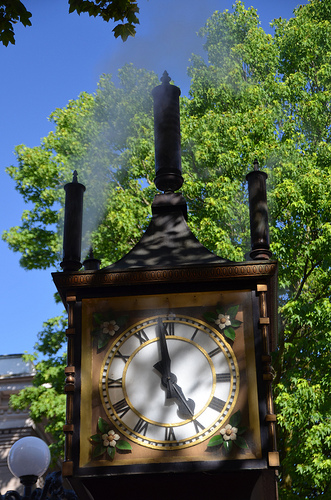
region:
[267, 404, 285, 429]
edge of a clock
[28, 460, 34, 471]
part of a bulb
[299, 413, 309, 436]
part of a tree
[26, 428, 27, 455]
edge of a light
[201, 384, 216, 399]
part of a clock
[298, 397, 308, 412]
part of a branch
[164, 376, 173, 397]
part of a watch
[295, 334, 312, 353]
part of a branch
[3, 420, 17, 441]
part of a clock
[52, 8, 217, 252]
steam in the air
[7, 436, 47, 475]
a white glass bulb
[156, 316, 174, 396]
long hand on a clock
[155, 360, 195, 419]
short hand on a clock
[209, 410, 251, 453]
green and white decorative flower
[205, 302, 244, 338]
green and white decorative flower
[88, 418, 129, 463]
green and white decorative flower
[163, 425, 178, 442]
roman numeral for 6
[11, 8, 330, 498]
a large green tree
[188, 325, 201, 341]
roman numeral for one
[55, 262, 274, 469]
Large clock on a pole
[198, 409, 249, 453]
Decorative flower on a clock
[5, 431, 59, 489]
Top of a lamp pole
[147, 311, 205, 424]
Hands on a large clock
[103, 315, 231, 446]
Roman numbers on a clock face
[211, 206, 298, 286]
Leaves of a tree in teh background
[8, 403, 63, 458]
Brick building in background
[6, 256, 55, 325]
Blue sky above a building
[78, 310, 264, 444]
Face of a clock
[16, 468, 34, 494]
Pole supporting a light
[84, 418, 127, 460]
Flower decoration in the corner of a clock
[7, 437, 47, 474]
Globe shaped light on the top of a post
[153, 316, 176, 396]
The minute hand on a clock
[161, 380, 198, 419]
The hour hand on a clock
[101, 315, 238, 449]
Black and white clock face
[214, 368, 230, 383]
Three on the clock in roman numerals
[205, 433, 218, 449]
Green leaf on a decorative flower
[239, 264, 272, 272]
Decorative trim on the top of a large clock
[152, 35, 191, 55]
Smoke against the blue sky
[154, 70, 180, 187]
Chimney or smoke vent on top of a clock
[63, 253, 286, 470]
A large wooden clock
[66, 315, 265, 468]
A clock carved from wood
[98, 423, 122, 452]
A white and yellow flower painted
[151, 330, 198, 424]
The hands on the clock are black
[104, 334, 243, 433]
Roman numerals on a clock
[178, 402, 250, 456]
Flowers carved on clock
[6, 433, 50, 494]
A white globe on a street light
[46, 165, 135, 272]
The clock blows steam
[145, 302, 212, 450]
It is almost five o'clock